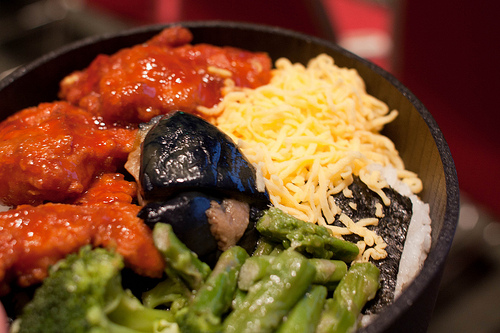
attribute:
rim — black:
[209, 25, 464, 325]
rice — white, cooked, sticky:
[242, 73, 359, 174]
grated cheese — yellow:
[249, 133, 402, 221]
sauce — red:
[59, 33, 276, 116]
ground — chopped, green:
[380, 105, 411, 144]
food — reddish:
[4, 30, 469, 331]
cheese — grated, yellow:
[244, 72, 394, 197]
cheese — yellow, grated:
[263, 84, 370, 166]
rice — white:
[396, 190, 433, 281]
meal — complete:
[1, 22, 433, 331]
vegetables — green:
[26, 193, 375, 328]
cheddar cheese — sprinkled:
[211, 57, 421, 219]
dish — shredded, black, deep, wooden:
[4, 21, 463, 331]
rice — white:
[318, 89, 337, 125]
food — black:
[131, 110, 268, 258]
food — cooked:
[1, 25, 431, 332]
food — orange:
[0, 30, 269, 310]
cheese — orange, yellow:
[196, 48, 427, 254]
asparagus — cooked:
[16, 205, 381, 331]